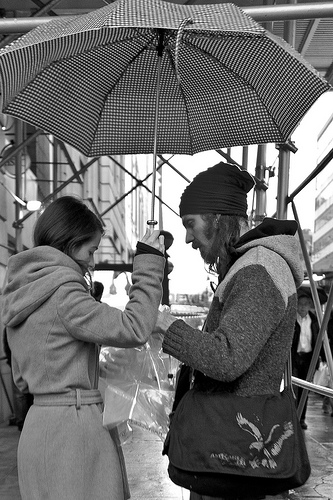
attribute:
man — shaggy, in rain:
[171, 169, 297, 498]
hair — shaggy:
[205, 210, 266, 271]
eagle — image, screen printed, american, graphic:
[233, 406, 289, 475]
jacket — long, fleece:
[213, 247, 292, 487]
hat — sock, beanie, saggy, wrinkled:
[190, 172, 246, 210]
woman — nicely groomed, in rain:
[10, 196, 123, 498]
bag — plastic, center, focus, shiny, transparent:
[112, 339, 168, 432]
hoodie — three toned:
[214, 238, 306, 393]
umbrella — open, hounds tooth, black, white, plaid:
[8, 3, 296, 145]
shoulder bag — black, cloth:
[165, 382, 309, 485]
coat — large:
[9, 253, 116, 499]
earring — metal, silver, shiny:
[213, 225, 218, 233]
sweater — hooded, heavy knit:
[187, 245, 296, 389]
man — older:
[293, 298, 317, 360]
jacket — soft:
[24, 230, 94, 498]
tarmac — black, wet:
[12, 414, 324, 499]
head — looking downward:
[37, 198, 122, 273]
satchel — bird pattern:
[154, 391, 313, 489]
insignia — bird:
[217, 406, 300, 475]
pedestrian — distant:
[291, 289, 312, 417]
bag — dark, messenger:
[169, 410, 282, 495]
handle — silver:
[147, 219, 157, 271]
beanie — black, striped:
[185, 164, 248, 212]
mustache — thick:
[187, 242, 202, 250]